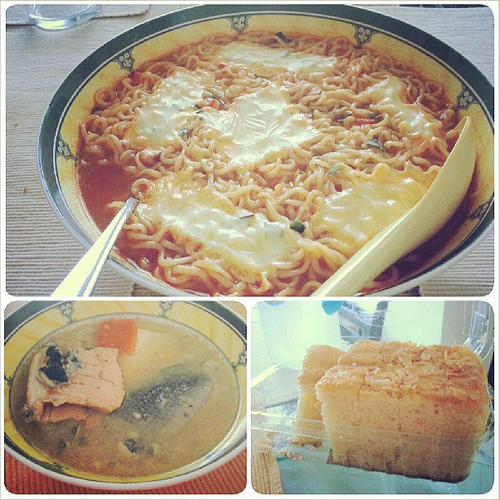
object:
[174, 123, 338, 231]
noodles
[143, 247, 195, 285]
noodles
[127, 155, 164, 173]
noodles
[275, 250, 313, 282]
noodles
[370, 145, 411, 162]
noodles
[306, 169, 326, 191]
noodles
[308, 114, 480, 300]
soup spoon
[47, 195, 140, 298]
metal spoon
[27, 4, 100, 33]
glass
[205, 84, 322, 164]
cheese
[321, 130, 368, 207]
ground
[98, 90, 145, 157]
noodles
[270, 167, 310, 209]
noodles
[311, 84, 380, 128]
noodles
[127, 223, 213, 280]
noodles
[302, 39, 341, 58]
noodles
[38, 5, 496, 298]
bowl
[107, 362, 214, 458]
fish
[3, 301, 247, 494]
bowl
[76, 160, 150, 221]
sauce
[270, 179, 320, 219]
noodles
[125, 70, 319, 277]
cheese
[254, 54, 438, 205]
noodles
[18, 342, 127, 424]
fish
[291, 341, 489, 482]
pastry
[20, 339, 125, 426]
meat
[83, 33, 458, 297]
noodles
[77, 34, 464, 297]
soup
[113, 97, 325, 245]
soup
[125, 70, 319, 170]
cheese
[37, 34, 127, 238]
rim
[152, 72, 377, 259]
noodles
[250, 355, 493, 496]
container